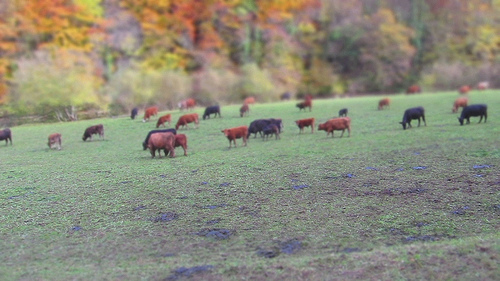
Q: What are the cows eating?
A: Grass.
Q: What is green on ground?
A: Grass.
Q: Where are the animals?
A: Field.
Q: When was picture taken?
A: Daytime.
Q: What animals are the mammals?
A: Cows.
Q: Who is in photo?
A: Cows.